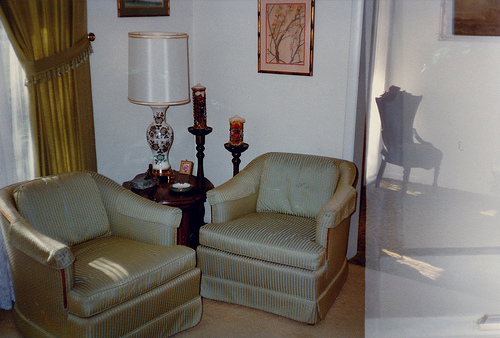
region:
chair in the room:
[201, 151, 348, 314]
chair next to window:
[7, 169, 212, 326]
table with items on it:
[135, 153, 207, 242]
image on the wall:
[248, 3, 326, 76]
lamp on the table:
[117, 27, 192, 179]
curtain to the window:
[2, 5, 122, 189]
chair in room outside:
[366, 78, 449, 212]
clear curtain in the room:
[359, 6, 498, 335]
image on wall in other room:
[431, 3, 499, 48]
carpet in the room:
[168, 255, 370, 336]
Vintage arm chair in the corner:
[373, 83, 443, 198]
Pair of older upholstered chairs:
[2, 145, 357, 336]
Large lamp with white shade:
[126, 28, 192, 184]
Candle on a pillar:
[185, 80, 213, 184]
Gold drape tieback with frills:
[20, 31, 96, 86]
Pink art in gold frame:
[253, 0, 315, 77]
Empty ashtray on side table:
[167, 179, 194, 193]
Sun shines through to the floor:
[379, 245, 448, 284]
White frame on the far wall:
[435, 0, 499, 45]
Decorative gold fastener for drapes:
[86, 30, 95, 42]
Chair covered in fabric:
[199, 151, 358, 326]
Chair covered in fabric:
[0, 167, 207, 334]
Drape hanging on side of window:
[1, 1, 119, 183]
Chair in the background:
[372, 76, 444, 210]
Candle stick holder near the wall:
[184, 82, 222, 185]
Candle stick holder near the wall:
[219, 112, 259, 176]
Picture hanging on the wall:
[247, 1, 322, 86]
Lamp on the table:
[119, 29, 199, 189]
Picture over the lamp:
[110, 1, 185, 22]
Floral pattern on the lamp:
[137, 103, 176, 175]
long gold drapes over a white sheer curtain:
[1, 2, 98, 174]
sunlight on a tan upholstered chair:
[90, 255, 132, 281]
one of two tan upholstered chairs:
[0, 172, 199, 336]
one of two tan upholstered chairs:
[200, 149, 357, 321]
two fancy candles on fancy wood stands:
[182, 82, 247, 192]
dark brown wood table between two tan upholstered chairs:
[123, 165, 210, 237]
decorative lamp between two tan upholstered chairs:
[125, 28, 191, 186]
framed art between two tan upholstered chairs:
[112, 0, 172, 20]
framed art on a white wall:
[252, 0, 315, 80]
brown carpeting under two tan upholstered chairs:
[2, 264, 357, 334]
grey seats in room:
[14, 148, 354, 336]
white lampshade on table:
[125, 23, 187, 133]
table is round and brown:
[125, 161, 217, 233]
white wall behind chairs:
[267, 71, 332, 142]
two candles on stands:
[174, 77, 245, 155]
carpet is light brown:
[224, 295, 282, 336]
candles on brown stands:
[182, 123, 240, 210]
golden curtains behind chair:
[18, 0, 109, 172]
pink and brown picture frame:
[268, 0, 340, 82]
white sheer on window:
[0, 60, 35, 158]